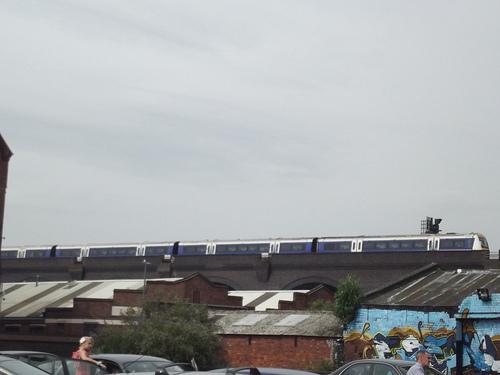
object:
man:
[405, 349, 430, 374]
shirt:
[407, 361, 424, 374]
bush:
[95, 294, 237, 366]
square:
[232, 314, 269, 326]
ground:
[414, 180, 427, 201]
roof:
[356, 262, 500, 311]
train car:
[314, 232, 432, 252]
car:
[54, 353, 186, 375]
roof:
[0, 275, 301, 324]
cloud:
[54, 16, 491, 211]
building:
[3, 274, 245, 349]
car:
[327, 359, 440, 375]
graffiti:
[343, 296, 500, 374]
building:
[344, 261, 499, 366]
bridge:
[0, 254, 499, 280]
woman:
[71, 336, 107, 375]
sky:
[0, 2, 484, 233]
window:
[414, 241, 425, 249]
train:
[0, 233, 491, 267]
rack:
[154, 361, 260, 374]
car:
[172, 367, 326, 375]